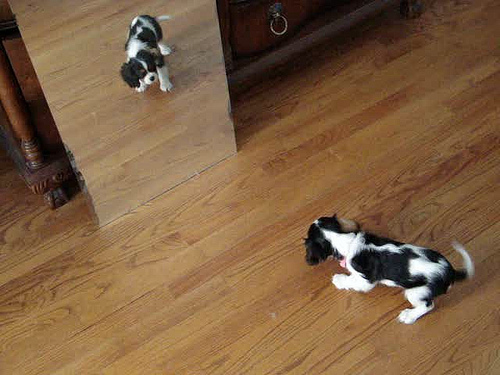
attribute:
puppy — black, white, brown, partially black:
[294, 208, 483, 334]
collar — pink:
[332, 228, 358, 268]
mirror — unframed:
[7, 0, 241, 232]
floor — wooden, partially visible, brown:
[2, 15, 499, 372]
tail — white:
[445, 239, 477, 287]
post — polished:
[0, 42, 41, 176]